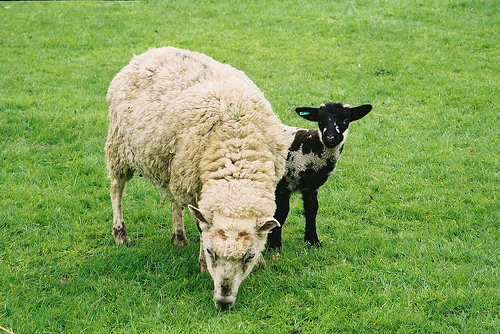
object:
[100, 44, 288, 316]
sheep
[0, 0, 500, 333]
field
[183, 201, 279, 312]
head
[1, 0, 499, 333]
grass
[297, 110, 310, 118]
tag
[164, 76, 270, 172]
fur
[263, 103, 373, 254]
sheep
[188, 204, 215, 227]
ear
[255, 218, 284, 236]
ear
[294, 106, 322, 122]
ear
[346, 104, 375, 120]
ear